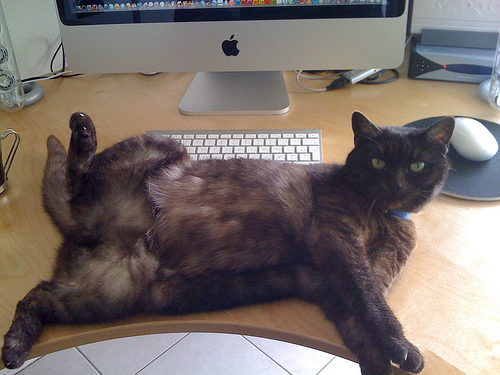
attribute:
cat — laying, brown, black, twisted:
[3, 111, 458, 373]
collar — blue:
[376, 200, 412, 222]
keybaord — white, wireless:
[144, 125, 325, 172]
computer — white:
[53, 0, 413, 76]